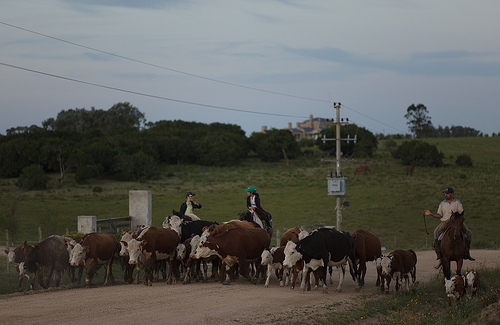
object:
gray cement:
[128, 190, 152, 231]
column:
[128, 190, 152, 231]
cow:
[21, 235, 73, 289]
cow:
[374, 254, 384, 286]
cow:
[200, 219, 255, 241]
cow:
[120, 226, 180, 286]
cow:
[260, 246, 286, 288]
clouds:
[215, 16, 415, 76]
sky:
[430, 89, 495, 120]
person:
[238, 186, 273, 238]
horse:
[237, 209, 273, 238]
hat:
[244, 186, 256, 192]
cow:
[282, 226, 360, 294]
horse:
[353, 166, 369, 176]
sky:
[41, 0, 464, 26]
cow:
[176, 238, 193, 282]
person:
[180, 191, 202, 220]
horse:
[173, 208, 202, 224]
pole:
[334, 103, 342, 233]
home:
[261, 114, 348, 141]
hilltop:
[1, 139, 500, 182]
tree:
[403, 103, 433, 140]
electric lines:
[0, 19, 339, 118]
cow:
[4, 247, 16, 264]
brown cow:
[120, 225, 181, 287]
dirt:
[58, 292, 203, 325]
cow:
[119, 229, 137, 285]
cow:
[444, 276, 465, 305]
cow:
[380, 249, 418, 292]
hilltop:
[373, 125, 498, 167]